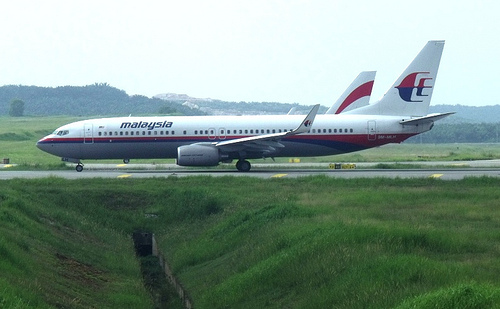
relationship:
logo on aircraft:
[394, 71, 433, 102] [35, 40, 456, 172]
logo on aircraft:
[118, 120, 177, 128] [35, 40, 456, 172]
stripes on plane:
[35, 132, 385, 145] [36, 38, 461, 178]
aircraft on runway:
[35, 40, 456, 172] [0, 165, 499, 178]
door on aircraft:
[82, 122, 94, 147] [35, 40, 456, 172]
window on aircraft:
[224, 127, 234, 134] [35, 40, 456, 172]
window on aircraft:
[219, 129, 226, 136] [35, 40, 456, 172]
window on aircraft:
[182, 129, 189, 134] [35, 40, 456, 172]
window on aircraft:
[349, 126, 356, 134] [35, 40, 456, 172]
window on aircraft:
[337, 128, 347, 136] [35, 40, 456, 172]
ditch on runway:
[132, 230, 196, 308] [0, 163, 498, 182]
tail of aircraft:
[349, 41, 445, 117] [55, 52, 455, 191]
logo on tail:
[395, 70, 429, 103] [343, 38, 443, 116]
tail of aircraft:
[343, 38, 443, 116] [36, 39, 452, 185]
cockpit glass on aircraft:
[48, 129, 70, 137] [32, 37, 457, 172]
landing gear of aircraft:
[73, 157, 85, 173] [32, 37, 457, 172]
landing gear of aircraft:
[236, 160, 251, 172] [32, 37, 457, 172]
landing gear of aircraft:
[228, 153, 255, 172] [32, 37, 457, 172]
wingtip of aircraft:
[293, 103, 320, 131] [33, 50, 433, 169]